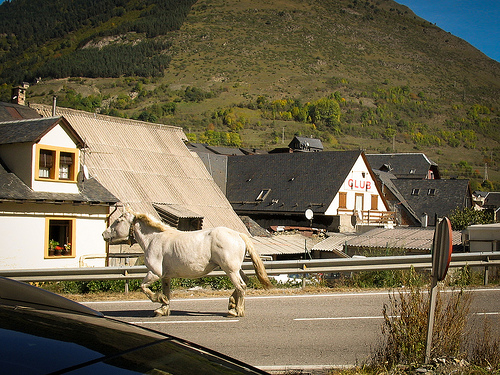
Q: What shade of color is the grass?
A: Green.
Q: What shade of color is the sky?
A: Blue.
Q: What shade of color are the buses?
A: Green.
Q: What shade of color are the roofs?
A: Black.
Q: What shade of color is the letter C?
A: Red.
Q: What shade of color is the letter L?
A: Red.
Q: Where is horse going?
A: Down road.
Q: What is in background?
A: Mountains.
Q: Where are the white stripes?
A: On road.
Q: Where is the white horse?
A: On the street.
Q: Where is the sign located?
A: Corner in the grass.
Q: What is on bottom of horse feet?
A: Hoofs.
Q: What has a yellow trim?
A: Windows.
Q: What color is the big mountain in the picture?
A: The big mountain is green.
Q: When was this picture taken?
A: This picture was taken in the day time.